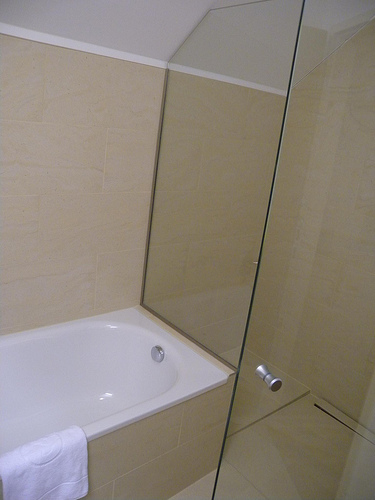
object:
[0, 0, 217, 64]
ceiling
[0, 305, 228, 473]
tub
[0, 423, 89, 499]
towel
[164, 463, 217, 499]
floor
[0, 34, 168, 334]
wall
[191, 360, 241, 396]
edge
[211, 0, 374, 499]
glass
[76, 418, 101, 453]
edge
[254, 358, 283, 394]
handle